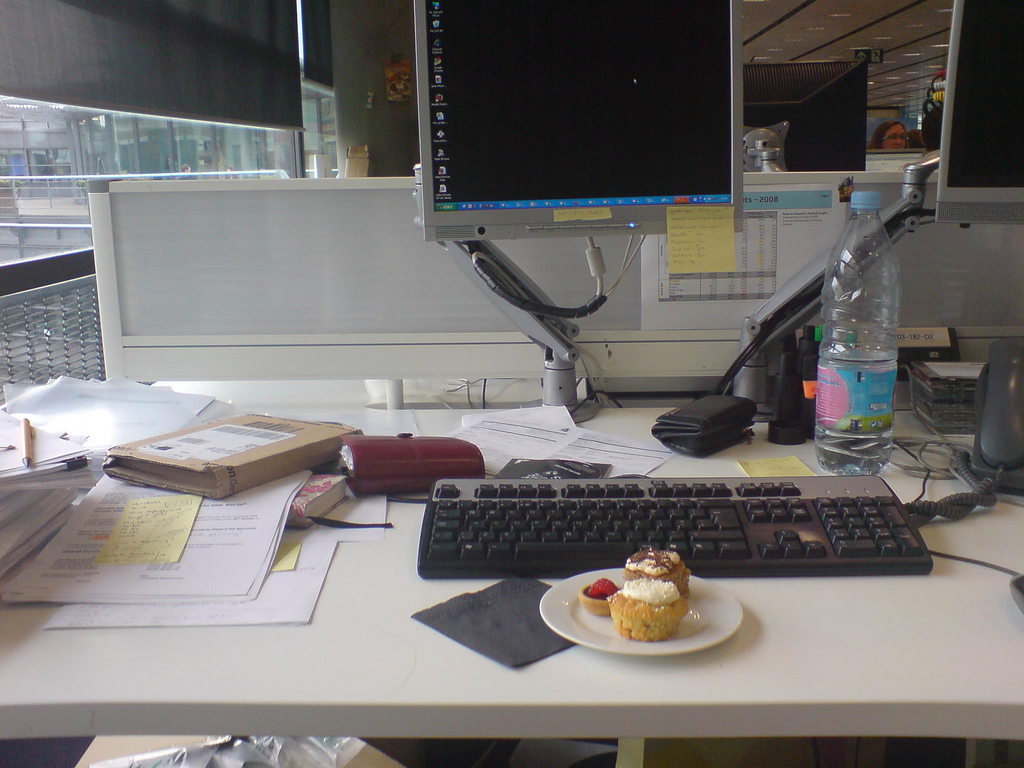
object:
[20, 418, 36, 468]
pen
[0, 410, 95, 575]
paper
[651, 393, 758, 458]
wallet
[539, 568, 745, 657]
plate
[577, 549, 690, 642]
cupcakes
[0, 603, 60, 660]
shadow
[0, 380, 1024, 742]
desk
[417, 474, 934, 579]
keyboard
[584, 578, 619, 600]
piece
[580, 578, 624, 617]
food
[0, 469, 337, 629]
paper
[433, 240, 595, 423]
cords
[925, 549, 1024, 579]
wire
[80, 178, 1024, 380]
partition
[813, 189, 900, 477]
bottle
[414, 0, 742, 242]
monitor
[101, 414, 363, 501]
package